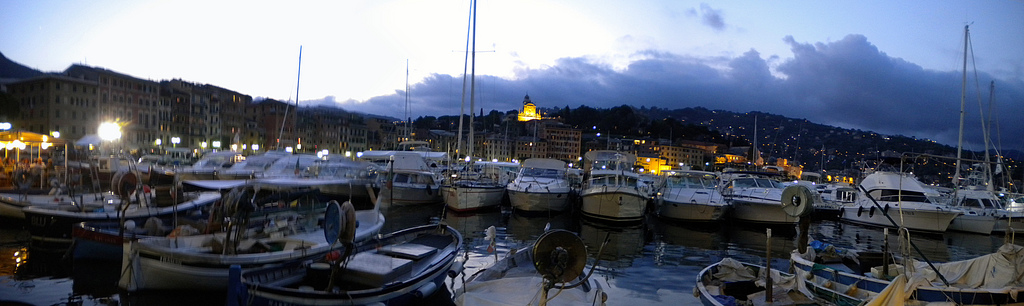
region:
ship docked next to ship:
[360, 160, 436, 209]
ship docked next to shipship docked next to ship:
[435, 160, 513, 220]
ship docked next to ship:
[507, 158, 585, 218]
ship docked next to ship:
[579, 162, 662, 227]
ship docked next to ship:
[651, 169, 734, 227]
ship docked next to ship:
[720, 185, 812, 232]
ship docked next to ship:
[846, 169, 963, 236]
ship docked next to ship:
[948, 183, 1020, 234]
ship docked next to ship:
[788, 243, 1022, 303]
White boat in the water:
[936, 179, 1019, 241]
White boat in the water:
[832, 161, 960, 244]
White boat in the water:
[652, 156, 736, 234]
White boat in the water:
[576, 148, 653, 226]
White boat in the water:
[503, 147, 568, 211]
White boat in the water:
[427, 148, 513, 229]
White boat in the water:
[351, 135, 449, 219]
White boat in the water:
[221, 208, 484, 301]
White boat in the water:
[683, 238, 836, 303]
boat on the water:
[115, 221, 271, 276]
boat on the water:
[368, 237, 473, 289]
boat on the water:
[709, 249, 757, 295]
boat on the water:
[803, 281, 886, 300]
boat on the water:
[826, 241, 997, 296]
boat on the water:
[68, 198, 193, 236]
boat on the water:
[200, 146, 321, 188]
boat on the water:
[377, 165, 438, 197]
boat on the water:
[512, 152, 564, 216]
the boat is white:
[499, 147, 585, 223]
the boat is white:
[581, 148, 662, 234]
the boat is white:
[651, 156, 729, 230]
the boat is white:
[275, 144, 378, 203]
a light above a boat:
[511, 81, 554, 151]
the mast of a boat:
[451, 0, 493, 178]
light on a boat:
[81, 107, 135, 183]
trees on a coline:
[411, 72, 980, 209]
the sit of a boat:
[335, 226, 441, 297]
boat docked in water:
[576, 158, 652, 223]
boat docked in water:
[651, 165, 729, 232]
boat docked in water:
[727, 161, 805, 228]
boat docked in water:
[840, 170, 959, 239]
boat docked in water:
[511, 152, 578, 221]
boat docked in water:
[446, 158, 509, 216]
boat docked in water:
[372, 158, 446, 205]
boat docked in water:
[129, 201, 387, 293]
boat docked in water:
[234, 217, 461, 300]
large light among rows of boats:
[85, 117, 131, 149]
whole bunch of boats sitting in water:
[0, 126, 1020, 304]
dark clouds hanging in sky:
[274, 0, 1018, 158]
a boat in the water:
[599, 120, 619, 210]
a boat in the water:
[695, 132, 776, 241]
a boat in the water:
[827, 177, 919, 254]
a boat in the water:
[502, 133, 541, 220]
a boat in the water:
[386, 136, 443, 228]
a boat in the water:
[281, 116, 355, 203]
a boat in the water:
[338, 185, 488, 304]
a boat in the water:
[726, 189, 857, 300]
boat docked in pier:
[576, 151, 637, 238]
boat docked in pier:
[643, 145, 723, 223]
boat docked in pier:
[839, 154, 941, 230]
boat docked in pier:
[435, 152, 518, 232]